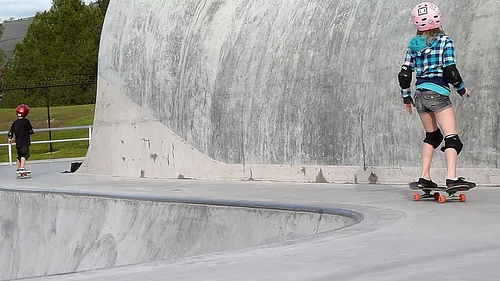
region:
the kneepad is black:
[413, 120, 494, 157]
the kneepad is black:
[400, 127, 487, 178]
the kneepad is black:
[432, 127, 463, 149]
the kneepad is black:
[413, 134, 483, 148]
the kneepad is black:
[422, 108, 472, 203]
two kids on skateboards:
[0, 2, 479, 258]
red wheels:
[406, 192, 478, 212]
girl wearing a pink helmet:
[401, 2, 455, 35]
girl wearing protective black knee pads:
[410, 120, 485, 155]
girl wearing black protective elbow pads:
[390, 52, 474, 88]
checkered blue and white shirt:
[404, 35, 459, 86]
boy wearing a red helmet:
[10, 102, 35, 116]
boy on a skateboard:
[7, 98, 44, 192]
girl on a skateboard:
[391, 4, 491, 210]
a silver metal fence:
[24, 122, 103, 159]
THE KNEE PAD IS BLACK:
[445, 140, 457, 158]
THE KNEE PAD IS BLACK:
[450, 118, 456, 171]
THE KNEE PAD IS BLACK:
[455, 134, 459, 154]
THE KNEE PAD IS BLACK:
[438, 135, 448, 153]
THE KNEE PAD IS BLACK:
[450, 135, 455, 153]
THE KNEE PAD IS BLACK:
[440, 145, 456, 147]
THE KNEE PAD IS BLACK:
[447, 138, 455, 143]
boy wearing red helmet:
[8, 94, 56, 190]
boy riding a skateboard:
[6, 93, 47, 193]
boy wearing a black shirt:
[4, 97, 45, 188]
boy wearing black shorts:
[5, 97, 44, 186]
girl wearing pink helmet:
[396, 1, 476, 211]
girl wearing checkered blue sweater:
[389, 5, 484, 212]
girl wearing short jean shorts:
[396, 4, 486, 224]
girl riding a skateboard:
[395, 3, 482, 223]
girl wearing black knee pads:
[392, 5, 499, 212]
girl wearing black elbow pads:
[390, 3, 479, 222]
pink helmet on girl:
[408, 0, 439, 31]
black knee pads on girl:
[420, 125, 460, 150]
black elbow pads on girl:
[395, 61, 460, 81]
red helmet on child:
[15, 100, 26, 115]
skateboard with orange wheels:
[406, 177, 466, 199]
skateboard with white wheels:
[15, 165, 30, 175]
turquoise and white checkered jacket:
[401, 30, 451, 85]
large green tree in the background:
[0, 0, 100, 102]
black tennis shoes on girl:
[415, 175, 475, 186]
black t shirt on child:
[8, 116, 30, 141]